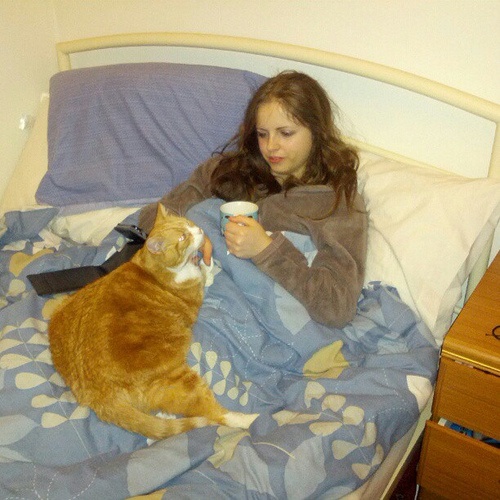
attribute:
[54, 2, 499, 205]
wall — white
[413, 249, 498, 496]
night stand — wooden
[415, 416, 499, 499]
drawer — open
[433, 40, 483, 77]
wall — white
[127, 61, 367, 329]
she — covered up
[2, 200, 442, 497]
comforter — blue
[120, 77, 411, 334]
woman — sick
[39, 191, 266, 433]
cat — orange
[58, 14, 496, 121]
wall — white, bedroom wall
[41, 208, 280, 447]
cat — fat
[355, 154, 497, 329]
bedsheet — white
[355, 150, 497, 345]
pillow — white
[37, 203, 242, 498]
cat — laying down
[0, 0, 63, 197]
wall — white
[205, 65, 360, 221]
hair — long, brown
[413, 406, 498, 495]
cabinate drawer — slightly open, wood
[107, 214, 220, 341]
cat — big, brown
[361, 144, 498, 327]
pillow — white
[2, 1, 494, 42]
wall — bedroom wall, white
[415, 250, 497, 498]
cabinet — wooden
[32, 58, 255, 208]
pillow — large, blue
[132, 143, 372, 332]
top — brown, fleece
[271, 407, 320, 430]
design — white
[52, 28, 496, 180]
bed post — white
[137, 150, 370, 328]
sweater — gray